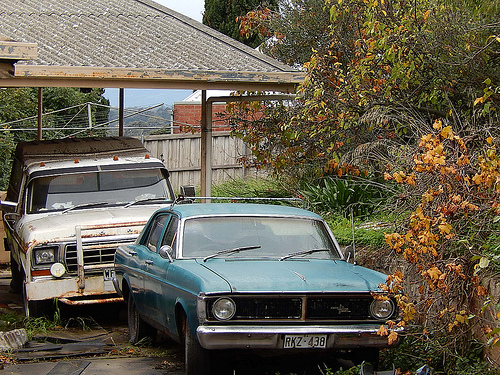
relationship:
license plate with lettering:
[280, 333, 328, 351] [284, 335, 301, 347]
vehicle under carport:
[1, 137, 181, 326] [3, 1, 315, 202]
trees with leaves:
[227, 1, 496, 371] [418, 186, 461, 270]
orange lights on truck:
[43, 154, 151, 165] [3, 136, 194, 323]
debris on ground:
[0, 328, 130, 359] [0, 268, 496, 370]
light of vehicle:
[211, 298, 237, 322] [103, 201, 403, 372]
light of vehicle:
[371, 298, 394, 321] [103, 201, 403, 372]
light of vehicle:
[28, 245, 61, 268] [3, 139, 196, 319]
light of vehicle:
[26, 268, 56, 277] [3, 139, 196, 319]